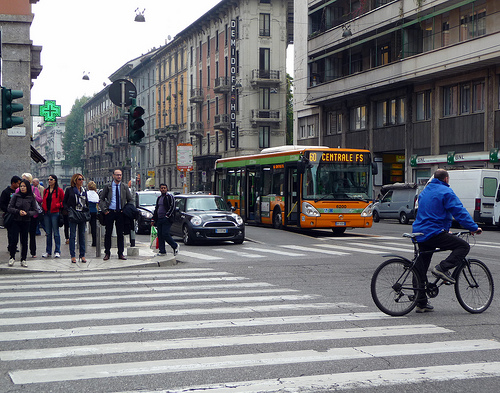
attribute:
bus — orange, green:
[213, 143, 373, 233]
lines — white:
[1, 234, 498, 392]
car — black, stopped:
[167, 192, 246, 246]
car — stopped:
[131, 190, 159, 233]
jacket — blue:
[412, 179, 479, 244]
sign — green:
[31, 99, 63, 123]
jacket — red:
[40, 186, 65, 215]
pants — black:
[415, 231, 469, 304]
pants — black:
[155, 221, 176, 250]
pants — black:
[105, 209, 126, 253]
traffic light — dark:
[125, 105, 147, 147]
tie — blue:
[114, 184, 121, 210]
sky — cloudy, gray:
[29, 1, 216, 133]